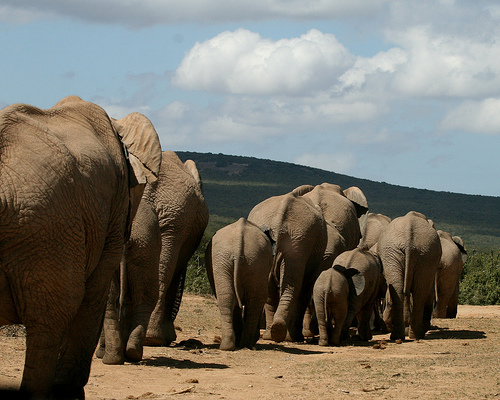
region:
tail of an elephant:
[220, 251, 253, 327]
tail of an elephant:
[320, 285, 332, 327]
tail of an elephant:
[266, 233, 281, 292]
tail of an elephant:
[392, 244, 413, 318]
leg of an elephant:
[403, 295, 440, 342]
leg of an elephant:
[211, 280, 237, 362]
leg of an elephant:
[263, 275, 305, 338]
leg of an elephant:
[315, 305, 331, 347]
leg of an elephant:
[380, 290, 406, 343]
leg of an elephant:
[98, 288, 126, 368]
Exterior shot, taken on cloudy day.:
[5, 3, 498, 396]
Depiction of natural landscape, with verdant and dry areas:
[0, 7, 490, 397]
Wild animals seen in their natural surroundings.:
[2, 3, 497, 396]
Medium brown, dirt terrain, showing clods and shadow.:
[172, 340, 474, 396]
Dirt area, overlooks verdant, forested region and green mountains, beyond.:
[185, 130, 496, 396]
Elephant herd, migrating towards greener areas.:
[3, 97, 464, 394]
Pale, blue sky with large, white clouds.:
[165, 7, 497, 178]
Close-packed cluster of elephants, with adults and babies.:
[215, 163, 473, 354]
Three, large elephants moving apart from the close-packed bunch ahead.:
[3, 95, 211, 395]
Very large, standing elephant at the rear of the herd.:
[1, 88, 168, 398]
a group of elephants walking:
[0, 92, 465, 399]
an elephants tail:
[231, 252, 246, 318]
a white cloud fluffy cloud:
[172, 25, 354, 95]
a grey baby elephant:
[310, 265, 365, 345]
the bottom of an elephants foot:
[268, 321, 288, 346]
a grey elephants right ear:
[342, 185, 367, 241]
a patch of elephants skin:
[20, 197, 75, 268]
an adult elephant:
[290, 181, 368, 234]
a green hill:
[176, 148, 497, 221]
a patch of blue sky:
[1, 30, 105, 61]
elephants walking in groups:
[53, 30, 498, 384]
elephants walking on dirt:
[26, 44, 473, 373]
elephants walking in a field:
[11, 43, 475, 393]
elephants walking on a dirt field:
[33, 43, 498, 395]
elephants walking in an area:
[14, 46, 484, 399]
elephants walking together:
[24, 26, 482, 398]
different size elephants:
[194, 108, 496, 396]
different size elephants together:
[204, 118, 459, 358]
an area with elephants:
[215, 81, 468, 399]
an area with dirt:
[116, 78, 485, 385]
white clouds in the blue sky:
[1, 2, 498, 156]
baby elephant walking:
[205, 213, 274, 356]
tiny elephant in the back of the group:
[310, 263, 360, 344]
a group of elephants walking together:
[0, 90, 480, 397]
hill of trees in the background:
[182, 150, 499, 254]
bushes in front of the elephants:
[174, 238, 499, 299]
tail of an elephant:
[232, 250, 245, 319]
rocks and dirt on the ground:
[2, 298, 499, 394]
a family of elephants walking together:
[207, 183, 470, 343]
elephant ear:
[115, 113, 165, 190]